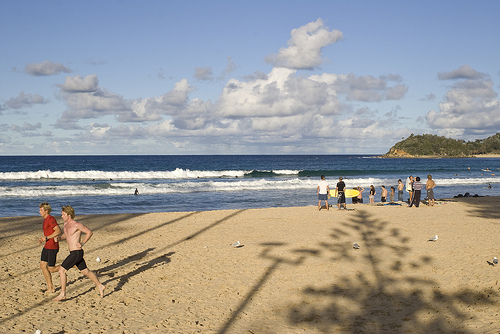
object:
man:
[33, 199, 73, 296]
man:
[53, 204, 108, 302]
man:
[333, 176, 347, 211]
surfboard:
[326, 188, 361, 198]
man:
[132, 187, 139, 197]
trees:
[406, 147, 421, 154]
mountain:
[379, 131, 497, 160]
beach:
[2, 200, 498, 332]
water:
[0, 151, 500, 212]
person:
[466, 165, 472, 171]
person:
[483, 167, 490, 173]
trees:
[286, 206, 500, 331]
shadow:
[299, 206, 464, 333]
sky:
[0, 0, 496, 160]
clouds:
[270, 17, 342, 74]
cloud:
[27, 60, 73, 79]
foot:
[98, 283, 107, 298]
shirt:
[41, 214, 59, 249]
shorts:
[62, 248, 87, 270]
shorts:
[40, 245, 59, 267]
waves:
[2, 169, 311, 178]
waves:
[2, 177, 494, 196]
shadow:
[65, 249, 174, 296]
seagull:
[428, 233, 439, 243]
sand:
[2, 201, 500, 332]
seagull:
[229, 239, 244, 249]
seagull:
[489, 256, 498, 269]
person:
[314, 174, 331, 209]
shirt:
[318, 179, 329, 195]